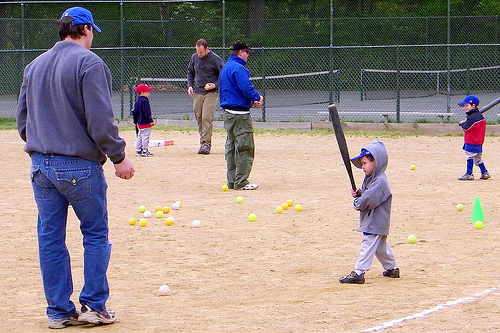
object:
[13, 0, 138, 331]
man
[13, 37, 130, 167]
shirt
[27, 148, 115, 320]
blue jeans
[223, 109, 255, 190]
pants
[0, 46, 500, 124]
net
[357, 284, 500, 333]
white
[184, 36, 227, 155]
man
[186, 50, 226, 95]
sweater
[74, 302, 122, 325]
shoe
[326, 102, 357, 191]
baseball bat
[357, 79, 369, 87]
nets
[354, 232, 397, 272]
pants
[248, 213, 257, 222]
ball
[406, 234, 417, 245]
ball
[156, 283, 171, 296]
ball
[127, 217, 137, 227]
ball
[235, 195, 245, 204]
ball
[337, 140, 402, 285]
boy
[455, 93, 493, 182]
boy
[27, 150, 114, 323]
jeans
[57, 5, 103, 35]
baseball cap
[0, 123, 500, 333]
field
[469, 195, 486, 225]
cone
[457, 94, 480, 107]
cap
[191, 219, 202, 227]
baseball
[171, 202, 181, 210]
baseball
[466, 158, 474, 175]
socks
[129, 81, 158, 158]
boy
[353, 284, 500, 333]
line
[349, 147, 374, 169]
hat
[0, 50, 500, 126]
field